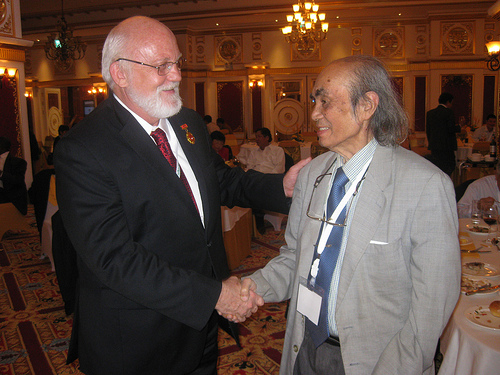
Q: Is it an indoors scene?
A: Yes, it is indoors.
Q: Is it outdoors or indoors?
A: It is indoors.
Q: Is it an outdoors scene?
A: No, it is indoors.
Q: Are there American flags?
A: No, there are no American flags.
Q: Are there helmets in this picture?
A: No, there are no helmets.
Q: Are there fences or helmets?
A: No, there are no helmets or fences.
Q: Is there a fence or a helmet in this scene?
A: No, there are no helmets or fences.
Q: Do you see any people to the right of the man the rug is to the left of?
A: Yes, there is a person to the right of the man.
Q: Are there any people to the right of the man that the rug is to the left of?
A: Yes, there is a person to the right of the man.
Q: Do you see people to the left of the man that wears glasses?
A: No, the person is to the right of the man.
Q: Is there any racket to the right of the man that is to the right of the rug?
A: No, there is a person to the right of the man.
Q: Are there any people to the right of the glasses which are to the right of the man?
A: Yes, there is a person to the right of the glasses.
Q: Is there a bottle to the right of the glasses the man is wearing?
A: No, there is a person to the right of the glasses.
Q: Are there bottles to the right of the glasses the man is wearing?
A: No, there is a person to the right of the glasses.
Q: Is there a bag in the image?
A: No, there are no bags.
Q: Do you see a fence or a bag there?
A: No, there are no bags or fences.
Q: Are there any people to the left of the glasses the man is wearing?
A: Yes, there is a person to the left of the glasses.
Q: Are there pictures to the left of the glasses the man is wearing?
A: No, there is a person to the left of the glasses.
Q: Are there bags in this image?
A: No, there are no bags.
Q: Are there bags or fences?
A: No, there are no bags or fences.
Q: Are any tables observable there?
A: Yes, there is a table.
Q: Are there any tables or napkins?
A: Yes, there is a table.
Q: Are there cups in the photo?
A: No, there are no cups.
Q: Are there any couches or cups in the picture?
A: No, there are no cups or couches.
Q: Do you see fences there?
A: No, there are no fences.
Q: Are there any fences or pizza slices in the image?
A: No, there are no fences or pizza slices.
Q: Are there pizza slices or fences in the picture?
A: No, there are no fences or pizza slices.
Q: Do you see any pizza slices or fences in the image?
A: No, there are no fences or pizza slices.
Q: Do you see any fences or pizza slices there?
A: No, there are no fences or pizza slices.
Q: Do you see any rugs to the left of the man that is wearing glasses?
A: Yes, there is a rug to the left of the man.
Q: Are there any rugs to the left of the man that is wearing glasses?
A: Yes, there is a rug to the left of the man.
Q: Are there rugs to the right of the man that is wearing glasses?
A: No, the rug is to the left of the man.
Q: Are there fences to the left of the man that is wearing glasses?
A: No, there is a rug to the left of the man.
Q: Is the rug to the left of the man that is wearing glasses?
A: Yes, the rug is to the left of the man.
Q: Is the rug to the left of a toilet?
A: No, the rug is to the left of the man.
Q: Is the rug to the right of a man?
A: No, the rug is to the left of a man.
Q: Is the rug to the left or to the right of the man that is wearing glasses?
A: The rug is to the left of the man.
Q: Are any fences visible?
A: No, there are no fences.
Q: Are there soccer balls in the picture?
A: No, there are no soccer balls.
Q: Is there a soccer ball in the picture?
A: No, there are no soccer balls.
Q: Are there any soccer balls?
A: No, there are no soccer balls.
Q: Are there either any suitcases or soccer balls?
A: No, there are no soccer balls or suitcases.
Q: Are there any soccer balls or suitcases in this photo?
A: No, there are no soccer balls or suitcases.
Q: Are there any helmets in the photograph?
A: No, there are no helmets.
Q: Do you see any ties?
A: Yes, there is a tie.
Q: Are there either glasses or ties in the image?
A: Yes, there is a tie.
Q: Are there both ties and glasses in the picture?
A: Yes, there are both a tie and glasses.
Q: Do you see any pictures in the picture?
A: No, there are no pictures.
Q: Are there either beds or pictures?
A: No, there are no pictures or beds.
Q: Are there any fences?
A: No, there are no fences.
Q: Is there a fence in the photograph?
A: No, there are no fences.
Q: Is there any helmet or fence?
A: No, there are no fences or helmets.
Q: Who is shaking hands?
A: The man is shaking hands.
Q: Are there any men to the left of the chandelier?
A: Yes, there is a man to the left of the chandelier.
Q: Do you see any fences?
A: No, there are no fences.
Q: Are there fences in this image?
A: No, there are no fences.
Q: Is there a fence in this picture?
A: No, there are no fences.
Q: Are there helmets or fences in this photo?
A: No, there are no fences or helmets.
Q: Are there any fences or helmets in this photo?
A: No, there are no fences or helmets.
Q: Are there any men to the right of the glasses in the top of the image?
A: Yes, there is a man to the right of the glasses.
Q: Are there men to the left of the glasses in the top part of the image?
A: No, the man is to the right of the glasses.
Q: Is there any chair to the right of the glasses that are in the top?
A: No, there is a man to the right of the glasses.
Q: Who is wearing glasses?
A: The man is wearing glasses.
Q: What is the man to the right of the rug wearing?
A: The man is wearing glasses.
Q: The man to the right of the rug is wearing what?
A: The man is wearing glasses.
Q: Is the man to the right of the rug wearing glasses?
A: Yes, the man is wearing glasses.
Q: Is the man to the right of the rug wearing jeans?
A: No, the man is wearing glasses.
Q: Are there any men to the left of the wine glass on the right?
A: Yes, there is a man to the left of the wineglass.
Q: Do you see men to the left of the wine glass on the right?
A: Yes, there is a man to the left of the wineglass.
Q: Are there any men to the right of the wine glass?
A: No, the man is to the left of the wine glass.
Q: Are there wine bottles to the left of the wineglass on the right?
A: No, there is a man to the left of the wineglass.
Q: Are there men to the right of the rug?
A: Yes, there is a man to the right of the rug.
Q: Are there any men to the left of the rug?
A: No, the man is to the right of the rug.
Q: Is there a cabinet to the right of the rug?
A: No, there is a man to the right of the rug.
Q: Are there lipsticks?
A: No, there are no lipsticks.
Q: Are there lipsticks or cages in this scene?
A: No, there are no lipsticks or cages.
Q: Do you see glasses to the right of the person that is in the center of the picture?
A: Yes, there are glasses to the right of the person.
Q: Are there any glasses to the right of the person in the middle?
A: Yes, there are glasses to the right of the person.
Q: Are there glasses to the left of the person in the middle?
A: No, the glasses are to the right of the person.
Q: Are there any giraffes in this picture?
A: No, there are no giraffes.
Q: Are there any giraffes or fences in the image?
A: No, there are no giraffes or fences.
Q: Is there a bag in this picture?
A: No, there are no bags.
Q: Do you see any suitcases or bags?
A: No, there are no bags or suitcases.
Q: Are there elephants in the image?
A: No, there are no elephants.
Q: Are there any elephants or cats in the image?
A: No, there are no elephants or cats.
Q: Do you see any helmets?
A: No, there are no helmets.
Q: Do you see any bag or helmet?
A: No, there are no helmets or bags.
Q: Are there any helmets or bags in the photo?
A: No, there are no helmets or bags.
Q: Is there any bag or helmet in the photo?
A: No, there are no helmets or bags.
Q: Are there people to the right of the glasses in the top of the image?
A: Yes, there is a person to the right of the glasses.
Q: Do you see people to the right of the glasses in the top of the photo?
A: Yes, there is a person to the right of the glasses.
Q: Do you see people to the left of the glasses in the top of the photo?
A: No, the person is to the right of the glasses.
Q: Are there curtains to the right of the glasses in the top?
A: No, there is a person to the right of the glasses.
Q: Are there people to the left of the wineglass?
A: Yes, there is a person to the left of the wineglass.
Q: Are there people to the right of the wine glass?
A: No, the person is to the left of the wine glass.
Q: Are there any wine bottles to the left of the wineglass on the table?
A: No, there is a person to the left of the wine glass.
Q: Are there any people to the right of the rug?
A: Yes, there is a person to the right of the rug.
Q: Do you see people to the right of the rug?
A: Yes, there is a person to the right of the rug.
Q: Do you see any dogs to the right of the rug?
A: No, there is a person to the right of the rug.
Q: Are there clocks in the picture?
A: No, there are no clocks.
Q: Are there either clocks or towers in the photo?
A: No, there are no clocks or towers.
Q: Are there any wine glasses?
A: Yes, there is a wine glass.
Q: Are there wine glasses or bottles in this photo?
A: Yes, there is a wine glass.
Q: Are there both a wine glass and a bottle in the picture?
A: No, there is a wine glass but no bottles.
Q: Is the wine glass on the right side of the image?
A: Yes, the wine glass is on the right of the image.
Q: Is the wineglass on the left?
A: No, the wineglass is on the right of the image.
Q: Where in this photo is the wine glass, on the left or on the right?
A: The wine glass is on the right of the image.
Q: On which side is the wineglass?
A: The wineglass is on the right of the image.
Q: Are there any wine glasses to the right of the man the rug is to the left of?
A: Yes, there is a wine glass to the right of the man.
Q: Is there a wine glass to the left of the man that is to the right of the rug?
A: No, the wine glass is to the right of the man.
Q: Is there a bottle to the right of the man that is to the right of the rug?
A: No, there is a wine glass to the right of the man.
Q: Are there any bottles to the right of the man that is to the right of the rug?
A: No, there is a wine glass to the right of the man.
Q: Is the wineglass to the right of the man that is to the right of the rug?
A: Yes, the wineglass is to the right of the man.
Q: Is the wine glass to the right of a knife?
A: No, the wine glass is to the right of the man.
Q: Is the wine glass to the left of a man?
A: No, the wine glass is to the right of a man.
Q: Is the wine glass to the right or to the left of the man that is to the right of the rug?
A: The wine glass is to the right of the man.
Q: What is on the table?
A: The wine glass is on the table.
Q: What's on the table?
A: The wine glass is on the table.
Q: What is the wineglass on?
A: The wineglass is on the table.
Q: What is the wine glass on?
A: The wineglass is on the table.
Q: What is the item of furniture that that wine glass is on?
A: The piece of furniture is a table.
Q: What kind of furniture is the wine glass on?
A: The wine glass is on the table.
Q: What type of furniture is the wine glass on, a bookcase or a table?
A: The wine glass is on a table.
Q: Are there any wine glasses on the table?
A: Yes, there is a wine glass on the table.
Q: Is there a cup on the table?
A: No, there is a wine glass on the table.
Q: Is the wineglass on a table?
A: Yes, the wineglass is on a table.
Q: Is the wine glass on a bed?
A: No, the wine glass is on a table.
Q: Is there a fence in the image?
A: No, there are no fences.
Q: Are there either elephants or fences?
A: No, there are no fences or elephants.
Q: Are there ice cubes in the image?
A: No, there are no ice cubes.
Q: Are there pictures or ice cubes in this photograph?
A: No, there are no ice cubes or pictures.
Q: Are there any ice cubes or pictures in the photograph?
A: No, there are no ice cubes or pictures.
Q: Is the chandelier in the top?
A: Yes, the chandelier is in the top of the image.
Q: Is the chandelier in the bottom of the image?
A: No, the chandelier is in the top of the image.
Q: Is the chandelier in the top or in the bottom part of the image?
A: The chandelier is in the top of the image.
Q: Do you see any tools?
A: No, there are no tools.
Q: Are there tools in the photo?
A: No, there are no tools.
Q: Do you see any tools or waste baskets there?
A: No, there are no tools or waste baskets.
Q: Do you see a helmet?
A: No, there are no helmets.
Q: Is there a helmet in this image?
A: No, there are no helmets.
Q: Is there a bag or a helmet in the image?
A: No, there are no helmets or bags.